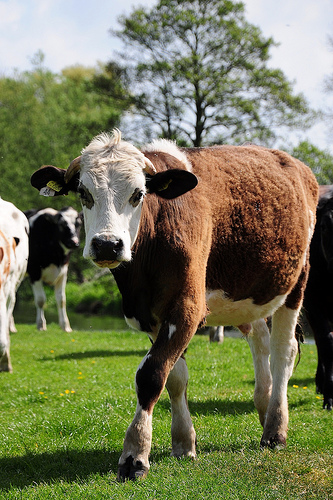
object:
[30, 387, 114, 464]
ground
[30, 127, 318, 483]
cow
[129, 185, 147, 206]
eye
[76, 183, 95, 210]
eye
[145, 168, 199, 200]
ear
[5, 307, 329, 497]
field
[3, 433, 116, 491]
shadow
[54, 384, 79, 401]
flower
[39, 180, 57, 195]
tag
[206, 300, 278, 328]
belly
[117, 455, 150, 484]
hoof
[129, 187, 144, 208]
brown ring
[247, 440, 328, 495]
dandelions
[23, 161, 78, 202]
air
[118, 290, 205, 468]
leg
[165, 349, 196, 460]
leg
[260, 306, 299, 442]
leg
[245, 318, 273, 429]
leg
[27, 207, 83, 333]
cow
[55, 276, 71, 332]
leg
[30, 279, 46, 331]
leg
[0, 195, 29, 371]
cow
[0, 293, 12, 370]
leg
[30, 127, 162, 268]
head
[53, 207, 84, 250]
head